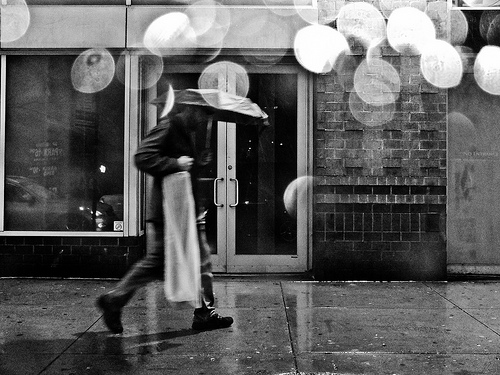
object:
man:
[95, 91, 237, 330]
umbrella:
[146, 83, 269, 125]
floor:
[3, 274, 500, 374]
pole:
[200, 118, 215, 166]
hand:
[175, 155, 197, 175]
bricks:
[317, 58, 442, 187]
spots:
[367, 7, 438, 59]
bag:
[163, 171, 202, 308]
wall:
[312, 49, 447, 279]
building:
[2, 0, 500, 277]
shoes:
[188, 303, 232, 334]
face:
[189, 107, 213, 136]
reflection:
[2, 173, 126, 233]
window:
[3, 53, 122, 230]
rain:
[2, 0, 500, 369]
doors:
[141, 61, 311, 276]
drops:
[290, 2, 500, 126]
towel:
[162, 170, 199, 310]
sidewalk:
[2, 72, 500, 277]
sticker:
[112, 218, 122, 230]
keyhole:
[227, 162, 232, 171]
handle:
[228, 176, 242, 206]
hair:
[185, 102, 209, 133]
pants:
[109, 220, 213, 315]